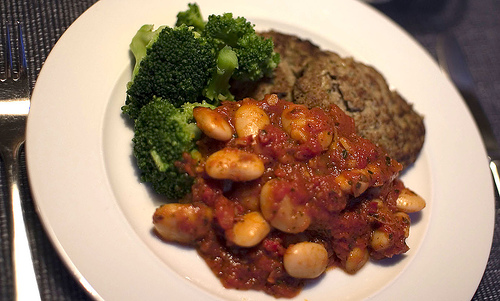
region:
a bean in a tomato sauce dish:
[147, 199, 209, 241]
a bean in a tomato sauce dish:
[226, 201, 266, 248]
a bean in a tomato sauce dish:
[286, 241, 327, 277]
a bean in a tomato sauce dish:
[341, 246, 369, 276]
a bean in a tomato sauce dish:
[390, 190, 429, 212]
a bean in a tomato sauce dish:
[291, 99, 331, 146]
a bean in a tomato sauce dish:
[233, 98, 272, 136]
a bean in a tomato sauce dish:
[195, 103, 230, 138]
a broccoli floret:
[188, 46, 238, 98]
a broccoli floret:
[131, 102, 191, 194]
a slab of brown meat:
[307, 55, 399, 132]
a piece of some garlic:
[251, 168, 302, 229]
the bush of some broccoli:
[124, 105, 182, 183]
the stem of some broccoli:
[202, 48, 237, 75]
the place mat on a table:
[5, 8, 56, 58]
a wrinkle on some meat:
[330, 76, 361, 111]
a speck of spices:
[224, 271, 251, 289]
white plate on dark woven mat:
[5, 5, 498, 296]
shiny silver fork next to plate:
[1, 12, 76, 293]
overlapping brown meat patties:
[265, 30, 425, 155]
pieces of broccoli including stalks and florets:
[120, 0, 275, 195]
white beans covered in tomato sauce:
[145, 100, 420, 295]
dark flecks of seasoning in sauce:
[230, 110, 355, 210]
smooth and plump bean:
[280, 240, 325, 280]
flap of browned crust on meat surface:
[316, 65, 386, 125]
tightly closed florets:
[151, 35, 198, 100]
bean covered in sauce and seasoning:
[281, 102, 328, 149]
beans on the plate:
[210, 107, 383, 250]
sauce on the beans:
[278, 144, 333, 184]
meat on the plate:
[288, 32, 424, 139]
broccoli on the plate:
[133, 23, 229, 145]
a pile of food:
[133, 20, 414, 283]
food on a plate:
[29, 3, 499, 299]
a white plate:
[30, 0, 499, 284]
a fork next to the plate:
[0, 8, 47, 299]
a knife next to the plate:
[436, 28, 498, 112]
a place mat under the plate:
[1, 3, 60, 43]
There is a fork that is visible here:
[4, 205, 36, 287]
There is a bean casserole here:
[236, 209, 257, 286]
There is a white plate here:
[53, 168, 86, 284]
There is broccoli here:
[170, 63, 191, 148]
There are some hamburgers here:
[340, 74, 367, 144]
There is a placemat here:
[40, 262, 50, 289]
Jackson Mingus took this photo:
[152, 84, 256, 254]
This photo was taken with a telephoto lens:
[178, 85, 260, 296]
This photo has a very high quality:
[173, 93, 238, 283]